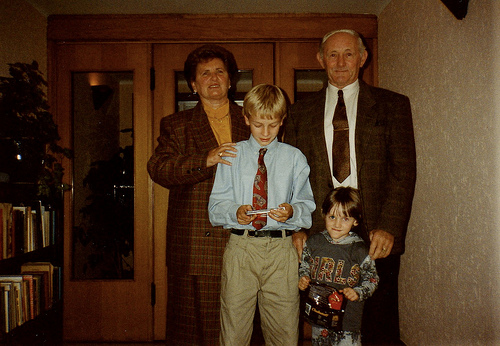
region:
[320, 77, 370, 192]
Man wearing white shirt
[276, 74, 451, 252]
Man wearing dark jacket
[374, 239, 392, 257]
Man wearing wedding ring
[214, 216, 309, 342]
Boy wearing tan pants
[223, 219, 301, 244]
Boy wearing dark belt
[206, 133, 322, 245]
Boy wearing blue shirt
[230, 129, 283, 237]
Boy wearing red tie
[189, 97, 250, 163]
Woman wearing yellow shirt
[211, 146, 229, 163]
Ring on womans finger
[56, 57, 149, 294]
Glass on wooden door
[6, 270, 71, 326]
books on second shelf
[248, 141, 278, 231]
boy's red tie with pattern design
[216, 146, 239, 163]
gold ring on woman's right hand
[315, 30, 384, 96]
smiling man with grey hair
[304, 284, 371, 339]
toy in girl's hands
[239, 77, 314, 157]
blonde haired boy looking down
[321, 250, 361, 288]
rls printed on girls shirt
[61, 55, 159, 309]
mirror on back of door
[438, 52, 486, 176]
beige area of wall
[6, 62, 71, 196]
plant on top of book shelf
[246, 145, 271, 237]
woman wearing a red tie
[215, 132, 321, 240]
boy wearing blue shirt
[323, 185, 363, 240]
girl with blond hair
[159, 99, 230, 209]
Woman a plaid jacket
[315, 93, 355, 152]
Man wearing a brown tie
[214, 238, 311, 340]
Boy wearing brown pants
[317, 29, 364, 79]
Man with gray hair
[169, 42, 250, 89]
woman with brown hair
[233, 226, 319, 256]
Boy with black belt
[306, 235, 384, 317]
Girl wearing a gray shirt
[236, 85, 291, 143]
The boys hair is blonde.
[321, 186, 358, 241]
The boys hair is brown.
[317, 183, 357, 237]
The boys hair is short.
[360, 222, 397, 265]
The man is wearing a ring.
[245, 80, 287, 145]
The boys hair is short.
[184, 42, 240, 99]
The woman's hair is brown.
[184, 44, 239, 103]
The womans hair is short.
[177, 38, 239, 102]
The woman is wearing earrings.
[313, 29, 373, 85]
The man's hair is grey.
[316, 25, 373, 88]
The man's hair is short.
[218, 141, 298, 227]
boy wearing a blue shirt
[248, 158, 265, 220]
boy wearing a red tie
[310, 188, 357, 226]
child with blond hair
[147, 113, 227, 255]
woman wearing a plaid jacket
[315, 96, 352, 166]
man wearing a brown tie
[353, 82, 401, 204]
man wearing a brown jacket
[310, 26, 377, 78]
man with gray hair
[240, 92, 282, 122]
boy with blond hair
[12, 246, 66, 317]
books on a shelf